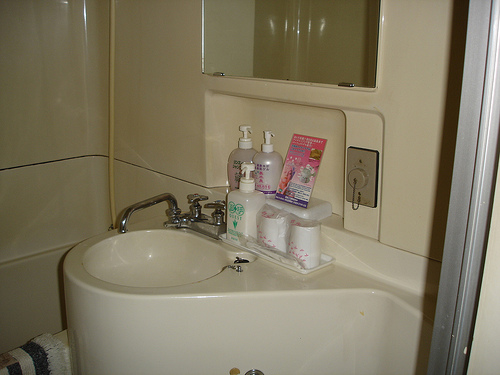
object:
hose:
[105, 3, 118, 232]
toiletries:
[223, 161, 323, 260]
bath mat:
[6, 332, 73, 375]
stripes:
[18, 340, 56, 373]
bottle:
[224, 161, 266, 240]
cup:
[255, 206, 293, 256]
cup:
[287, 217, 322, 271]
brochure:
[272, 130, 330, 210]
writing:
[226, 199, 246, 231]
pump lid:
[237, 123, 255, 150]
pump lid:
[257, 126, 280, 153]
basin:
[80, 227, 255, 289]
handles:
[200, 197, 228, 227]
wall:
[61, 273, 437, 373]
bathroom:
[3, 2, 499, 373]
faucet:
[111, 189, 184, 234]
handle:
[183, 189, 207, 221]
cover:
[345, 165, 370, 211]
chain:
[346, 181, 363, 211]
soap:
[262, 193, 332, 224]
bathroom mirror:
[200, 0, 381, 90]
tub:
[1, 243, 78, 371]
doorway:
[427, 0, 497, 373]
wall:
[110, 0, 457, 298]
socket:
[343, 145, 379, 212]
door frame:
[424, 1, 497, 372]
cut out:
[204, 90, 347, 231]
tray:
[217, 225, 334, 274]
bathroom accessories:
[224, 126, 259, 192]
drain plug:
[232, 254, 249, 265]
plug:
[341, 144, 378, 210]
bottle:
[252, 130, 285, 196]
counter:
[59, 206, 435, 320]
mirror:
[197, 2, 382, 92]